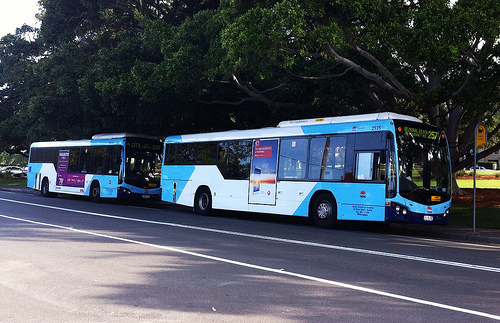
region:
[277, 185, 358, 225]
the wheels on a bus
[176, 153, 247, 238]
the back wheels on a bus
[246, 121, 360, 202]
the side windows on a bus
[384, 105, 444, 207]
the windshield on a bus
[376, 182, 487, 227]
the headlight on a bus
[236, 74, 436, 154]
the top of a bus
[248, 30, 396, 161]
a bus near a tree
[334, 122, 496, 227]
a bus near a pole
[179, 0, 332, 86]
green leaves on a tree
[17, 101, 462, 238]
two buses parked next to sidewalk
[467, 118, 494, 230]
sign on pole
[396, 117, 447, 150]
digital window on top of bus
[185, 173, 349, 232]
two tires on side of bus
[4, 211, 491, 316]
white lines on street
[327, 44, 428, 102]
tree branches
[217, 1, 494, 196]
tree on sidewalk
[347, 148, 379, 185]
window on side of bus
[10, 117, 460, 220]
two buses on the street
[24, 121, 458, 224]
two buses waiting to load customers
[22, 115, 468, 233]
two buses during a lay over on street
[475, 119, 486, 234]
yellow bus stop sign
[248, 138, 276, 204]
advertisement on the side of the bus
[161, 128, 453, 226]
large passenger bus is white and blue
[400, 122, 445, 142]
green-lit route sign on front of bus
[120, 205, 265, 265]
white lines painted on road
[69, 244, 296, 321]
shadows of trees cast on the pavement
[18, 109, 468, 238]
two city buses side by side on the road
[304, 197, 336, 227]
front tire of one of the buses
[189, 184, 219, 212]
back tire of the first bus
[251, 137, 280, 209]
large advertisement on the side of the bus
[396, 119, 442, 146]
yellow destination indicator sign on front of bus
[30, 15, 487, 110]
many large green and leafy trees behind the bus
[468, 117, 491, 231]
silver pole with a yellow sign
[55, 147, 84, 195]
purple advertisement on the side of the bus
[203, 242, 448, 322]
two white lines painted in the street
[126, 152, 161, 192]
front windshield of the second bus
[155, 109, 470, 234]
a blue and white bus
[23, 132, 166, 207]
a blue and white bus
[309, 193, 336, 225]
a wheel on a bus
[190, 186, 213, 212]
a wheel on a bus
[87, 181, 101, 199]
a wheel on a bus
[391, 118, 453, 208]
the windshield of a bus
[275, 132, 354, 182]
the window of a bus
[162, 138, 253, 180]
a group of windows on a bus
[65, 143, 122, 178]
a group of windows on a bus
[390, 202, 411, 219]
the headlights of a bus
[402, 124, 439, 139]
Green sign on front of bus.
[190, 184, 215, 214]
Back tire on right side of bus.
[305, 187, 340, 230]
Front tire on right side of bus.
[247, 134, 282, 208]
Ad on right side of bus.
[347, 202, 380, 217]
Black lettering on right side of bus.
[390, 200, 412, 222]
Headlight on front of bus.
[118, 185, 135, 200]
Headlight on front of second bus.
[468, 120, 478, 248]
Metal pole holding yellow street sign.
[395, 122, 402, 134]
Red light on front window of bus.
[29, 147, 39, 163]
a window on a bus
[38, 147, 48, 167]
a window on a bus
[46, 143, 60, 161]
a window on a bus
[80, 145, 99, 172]
a window on a bus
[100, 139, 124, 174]
a window on a bus